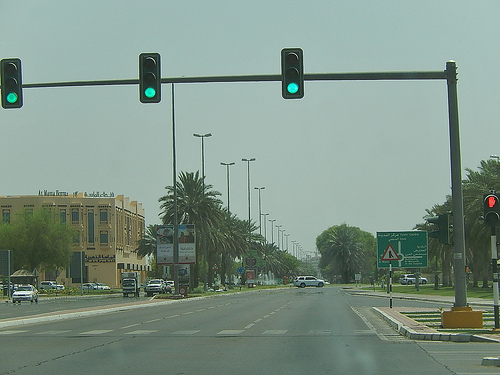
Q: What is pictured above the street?
A: Three green traffic lights.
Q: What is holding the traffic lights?
A: A pole.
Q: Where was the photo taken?
A: On the street.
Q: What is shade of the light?
A: Green.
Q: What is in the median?
A: Palm tree.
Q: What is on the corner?
A: Stop light.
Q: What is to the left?
A: Building.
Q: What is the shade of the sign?
A: Green.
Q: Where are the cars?
A: Road.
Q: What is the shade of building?
A: Brown.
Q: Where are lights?
A: In a row.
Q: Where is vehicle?
A: On street.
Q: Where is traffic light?
A: On pole.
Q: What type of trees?
A: Palm.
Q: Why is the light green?
A: Means go.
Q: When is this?
A: Afternoon.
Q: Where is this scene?
A: Street.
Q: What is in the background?
A: Cars.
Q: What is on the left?
A: Buildings.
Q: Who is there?
A: No one.